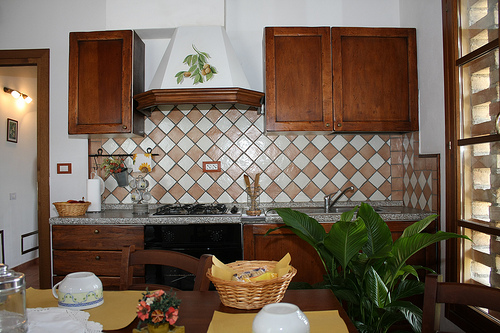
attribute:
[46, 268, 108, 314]
cup — upside down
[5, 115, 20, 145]
picture — framed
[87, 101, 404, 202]
tile — brown, white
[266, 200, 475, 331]
plant — large, green, leafy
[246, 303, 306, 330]
bowl — upside down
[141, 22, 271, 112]
hood — oven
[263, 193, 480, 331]
lilly — very big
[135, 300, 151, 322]
flower — pink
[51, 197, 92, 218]
basket — wicker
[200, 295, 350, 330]
mat — yellow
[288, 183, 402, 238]
sink — metal, kitchen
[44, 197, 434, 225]
counter — kitchen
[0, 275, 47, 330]
jar — glass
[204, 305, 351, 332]
placemat — light, brown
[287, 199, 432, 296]
plant — green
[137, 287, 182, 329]
bouquet — small, plastic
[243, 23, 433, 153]
cabinets — brown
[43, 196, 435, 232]
counter — kitchen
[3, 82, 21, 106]
fixture — light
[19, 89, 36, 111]
fixture — light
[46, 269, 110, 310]
cup — large, upside down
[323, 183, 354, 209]
faucet — kitchen, metal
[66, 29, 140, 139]
cabinet — brown, kitchen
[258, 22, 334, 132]
cabinet — brown, kitchen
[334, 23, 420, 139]
cabinet — brown, kitchen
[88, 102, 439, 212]
backsplash — kitchen